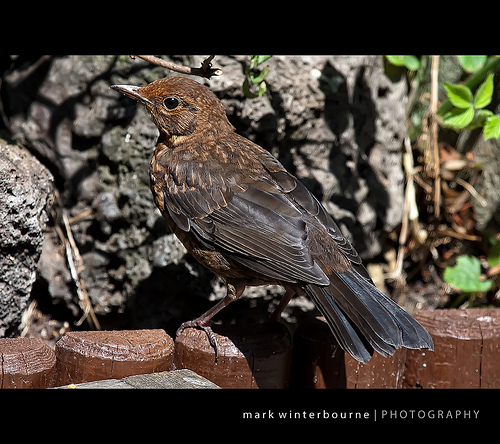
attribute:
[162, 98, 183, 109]
eye — below the leaf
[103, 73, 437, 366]
bird — rust colored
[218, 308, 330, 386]
shade — black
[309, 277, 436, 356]
tail — brown, flat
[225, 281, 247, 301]
knee — light brown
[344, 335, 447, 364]
feather — pointed, below bird, below bush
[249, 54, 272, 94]
leaf — bright green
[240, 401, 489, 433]
graphic — white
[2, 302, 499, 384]
poles — brown, half circles, wood, wooden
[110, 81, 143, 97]
beak — black, pointed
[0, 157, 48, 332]
rocks — grey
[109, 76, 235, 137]
head — round